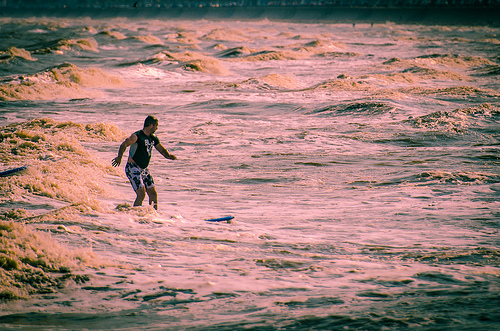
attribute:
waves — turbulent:
[29, 112, 129, 138]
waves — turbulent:
[12, 139, 89, 168]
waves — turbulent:
[34, 201, 99, 218]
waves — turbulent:
[0, 223, 88, 265]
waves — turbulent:
[2, 266, 94, 296]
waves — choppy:
[1, 0, 498, 329]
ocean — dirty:
[184, 53, 488, 214]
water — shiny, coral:
[0, 19, 498, 327]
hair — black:
[136, 112, 160, 129]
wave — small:
[305, 61, 362, 101]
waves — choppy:
[173, 26, 367, 109]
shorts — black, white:
[103, 148, 179, 190]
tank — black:
[131, 130, 157, 169]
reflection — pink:
[212, 147, 274, 214]